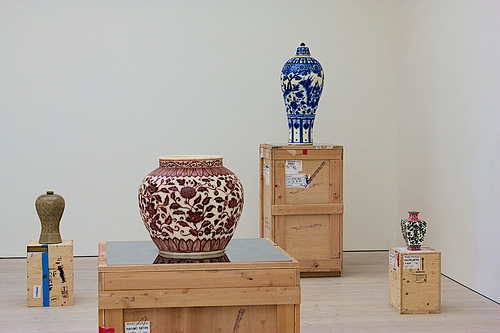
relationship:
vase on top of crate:
[281, 41, 324, 145] [259, 143, 345, 279]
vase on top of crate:
[137, 153, 246, 264] [98, 238, 298, 332]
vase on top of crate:
[37, 191, 67, 246] [28, 237, 76, 304]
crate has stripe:
[28, 237, 76, 304] [42, 242, 51, 307]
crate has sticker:
[259, 143, 345, 279] [286, 174, 311, 190]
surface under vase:
[103, 237, 293, 266] [137, 153, 246, 264]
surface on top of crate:
[103, 237, 293, 266] [98, 238, 298, 332]